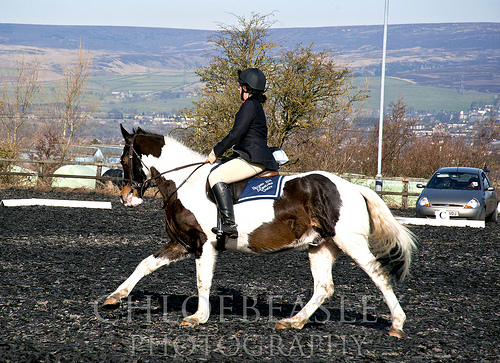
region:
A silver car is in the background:
[23, 37, 486, 348]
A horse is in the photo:
[102, 92, 420, 335]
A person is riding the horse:
[93, 65, 440, 317]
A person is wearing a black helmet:
[140, 41, 405, 257]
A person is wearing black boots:
[120, 62, 383, 358]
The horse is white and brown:
[93, 92, 450, 358]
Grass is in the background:
[41, 69, 481, 251]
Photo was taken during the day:
[29, 48, 474, 303]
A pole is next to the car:
[321, 28, 498, 268]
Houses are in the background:
[78, 55, 483, 165]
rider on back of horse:
[95, 66, 400, 336]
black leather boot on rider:
[208, 177, 238, 240]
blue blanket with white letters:
[240, 172, 295, 207]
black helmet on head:
[230, 62, 275, 103]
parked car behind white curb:
[409, 156, 492, 230]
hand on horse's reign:
[157, 151, 217, 193]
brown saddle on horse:
[252, 165, 287, 186]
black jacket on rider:
[215, 93, 282, 179]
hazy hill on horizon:
[110, 22, 217, 69]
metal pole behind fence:
[370, 46, 395, 196]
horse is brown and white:
[103, 79, 446, 361]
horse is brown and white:
[91, 117, 475, 337]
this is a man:
[209, 61, 276, 177]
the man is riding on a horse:
[126, 118, 402, 343]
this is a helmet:
[243, 68, 257, 81]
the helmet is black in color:
[249, 69, 256, 81]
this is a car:
[426, 166, 480, 214]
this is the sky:
[113, 5, 193, 22]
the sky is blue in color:
[68, 5, 112, 15]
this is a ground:
[14, 220, 79, 302]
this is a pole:
[373, 18, 395, 164]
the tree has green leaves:
[275, 70, 309, 92]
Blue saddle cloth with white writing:
[240, 160, 285, 214]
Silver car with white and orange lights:
[411, 150, 494, 241]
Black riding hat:
[220, 62, 273, 94]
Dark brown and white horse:
[93, 109, 419, 350]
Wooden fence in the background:
[10, 150, 107, 200]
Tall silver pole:
[371, 0, 393, 177]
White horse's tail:
[348, 176, 424, 286]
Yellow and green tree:
[184, 20, 358, 172]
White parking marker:
[2, 185, 115, 222]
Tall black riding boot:
[200, 174, 246, 252]